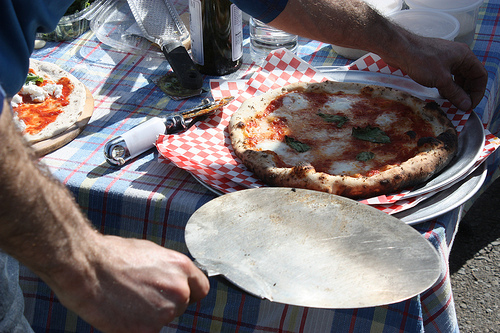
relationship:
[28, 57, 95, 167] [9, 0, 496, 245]
pizza laying on table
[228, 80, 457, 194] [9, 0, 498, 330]
pizza laying on table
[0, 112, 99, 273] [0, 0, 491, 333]
arm belonging to man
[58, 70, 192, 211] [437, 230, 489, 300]
table sitting in front of wall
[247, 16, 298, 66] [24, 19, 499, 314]
water bottle sitting atop table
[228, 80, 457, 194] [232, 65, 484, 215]
pizza laying on tray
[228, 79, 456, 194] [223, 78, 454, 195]
crust covering pie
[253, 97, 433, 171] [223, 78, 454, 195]
sauce covering pie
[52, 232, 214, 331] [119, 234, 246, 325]
hand holding handle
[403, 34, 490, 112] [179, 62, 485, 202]
hand grabbing pizza pan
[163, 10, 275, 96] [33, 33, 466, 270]
bottle standing on table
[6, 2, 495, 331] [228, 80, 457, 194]
tablecloth laying underneath pizza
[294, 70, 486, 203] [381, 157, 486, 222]
pan laying atop pan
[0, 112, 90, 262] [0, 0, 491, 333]
arm belonging to man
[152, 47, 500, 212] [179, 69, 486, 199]
paper laying on pizza pan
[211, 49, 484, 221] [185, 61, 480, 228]
paper laying on pizza tray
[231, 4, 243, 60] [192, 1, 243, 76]
white label glued on bottle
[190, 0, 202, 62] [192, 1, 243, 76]
white label glued on bottle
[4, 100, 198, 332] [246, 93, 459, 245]
man serving pizza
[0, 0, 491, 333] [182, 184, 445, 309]
man holding tray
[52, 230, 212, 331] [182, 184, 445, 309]
hand holding tray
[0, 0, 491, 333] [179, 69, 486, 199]
man holding pizza pan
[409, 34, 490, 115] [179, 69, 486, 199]
hand holding pizza pan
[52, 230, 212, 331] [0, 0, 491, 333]
hand belonging to man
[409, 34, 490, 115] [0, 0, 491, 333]
hand belonging to man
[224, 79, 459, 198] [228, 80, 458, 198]
crust on pizza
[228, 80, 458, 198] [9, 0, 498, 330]
pizza on table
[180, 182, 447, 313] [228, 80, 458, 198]
pan for carrying pizza